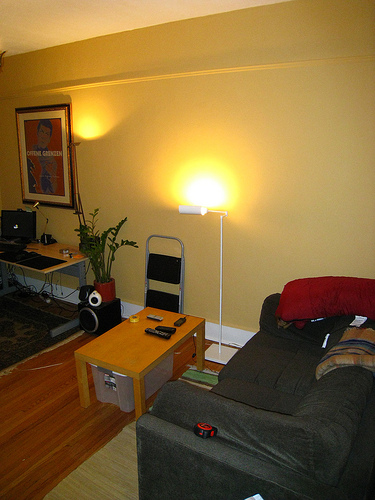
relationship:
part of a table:
[126, 354, 146, 368] [71, 304, 206, 421]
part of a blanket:
[271, 389, 281, 393] [275, 276, 375, 320]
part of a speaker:
[107, 314, 112, 324] [71, 291, 119, 337]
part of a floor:
[119, 459, 134, 473] [80, 439, 131, 478]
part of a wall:
[228, 303, 240, 315] [225, 308, 233, 325]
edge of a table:
[146, 302, 206, 324] [3, 215, 94, 278]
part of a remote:
[150, 327, 155, 331] [145, 328, 155, 334]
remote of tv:
[141, 321, 177, 354] [4, 214, 36, 253]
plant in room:
[72, 208, 138, 285] [4, 1, 372, 491]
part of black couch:
[260, 355, 289, 384] [136, 292, 373, 498]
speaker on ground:
[60, 258, 133, 346] [1, 273, 237, 498]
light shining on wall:
[156, 157, 237, 206] [253, 99, 366, 199]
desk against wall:
[0, 239, 84, 339] [5, 54, 362, 339]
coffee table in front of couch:
[74, 307, 206, 421] [196, 258, 352, 488]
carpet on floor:
[1, 294, 84, 380] [0, 375, 76, 467]